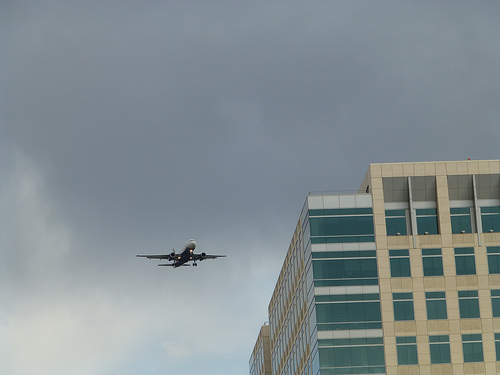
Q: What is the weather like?
A: It is cloudy.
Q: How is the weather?
A: It is cloudy.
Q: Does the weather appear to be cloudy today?
A: Yes, it is cloudy.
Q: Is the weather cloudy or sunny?
A: It is cloudy.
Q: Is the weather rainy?
A: No, it is cloudy.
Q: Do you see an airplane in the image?
A: Yes, there is an airplane.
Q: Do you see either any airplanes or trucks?
A: Yes, there is an airplane.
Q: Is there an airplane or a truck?
A: Yes, there is an airplane.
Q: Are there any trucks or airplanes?
A: Yes, there is an airplane.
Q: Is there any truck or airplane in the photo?
A: Yes, there is an airplane.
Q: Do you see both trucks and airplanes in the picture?
A: No, there is an airplane but no trucks.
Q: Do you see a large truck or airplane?
A: Yes, there is a large airplane.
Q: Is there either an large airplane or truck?
A: Yes, there is a large airplane.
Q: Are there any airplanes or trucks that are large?
A: Yes, the airplane is large.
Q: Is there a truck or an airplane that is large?
A: Yes, the airplane is large.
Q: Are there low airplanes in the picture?
A: Yes, there is a low airplane.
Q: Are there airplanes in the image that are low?
A: Yes, there is an airplane that is low.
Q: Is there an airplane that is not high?
A: Yes, there is a low airplane.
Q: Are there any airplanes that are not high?
A: Yes, there is a low airplane.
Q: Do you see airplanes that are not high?
A: Yes, there is a low airplane.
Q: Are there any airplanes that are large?
A: Yes, there is a large airplane.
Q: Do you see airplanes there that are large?
A: Yes, there is an airplane that is large.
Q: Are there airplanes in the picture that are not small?
A: Yes, there is a large airplane.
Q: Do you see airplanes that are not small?
A: Yes, there is a large airplane.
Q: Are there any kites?
A: No, there are no kites.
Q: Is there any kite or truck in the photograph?
A: No, there are no kites or trucks.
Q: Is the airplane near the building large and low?
A: Yes, the airplane is large and low.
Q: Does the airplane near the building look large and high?
A: No, the plane is large but low.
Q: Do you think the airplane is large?
A: Yes, the airplane is large.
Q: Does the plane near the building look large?
A: Yes, the airplane is large.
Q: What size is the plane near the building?
A: The plane is large.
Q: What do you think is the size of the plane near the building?
A: The plane is large.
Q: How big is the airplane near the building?
A: The plane is large.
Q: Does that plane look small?
A: No, the plane is large.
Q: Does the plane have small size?
A: No, the plane is large.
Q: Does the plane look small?
A: No, the plane is large.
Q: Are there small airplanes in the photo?
A: No, there is an airplane but it is large.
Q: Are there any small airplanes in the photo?
A: No, there is an airplane but it is large.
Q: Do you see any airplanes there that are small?
A: No, there is an airplane but it is large.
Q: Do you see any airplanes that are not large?
A: No, there is an airplane but it is large.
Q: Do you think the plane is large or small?
A: The plane is large.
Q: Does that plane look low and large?
A: Yes, the plane is low and large.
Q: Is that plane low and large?
A: Yes, the plane is low and large.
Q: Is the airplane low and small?
A: No, the airplane is low but large.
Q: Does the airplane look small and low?
A: No, the airplane is low but large.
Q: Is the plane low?
A: Yes, the plane is low.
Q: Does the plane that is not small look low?
A: Yes, the plane is low.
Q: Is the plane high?
A: No, the plane is low.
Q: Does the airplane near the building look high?
A: No, the airplane is low.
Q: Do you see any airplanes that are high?
A: No, there is an airplane but it is low.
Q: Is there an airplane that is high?
A: No, there is an airplane but it is low.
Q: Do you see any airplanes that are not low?
A: No, there is an airplane but it is low.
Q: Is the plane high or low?
A: The plane is low.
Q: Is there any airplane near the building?
A: Yes, there is an airplane near the building.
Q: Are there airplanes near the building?
A: Yes, there is an airplane near the building.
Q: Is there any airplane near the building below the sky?
A: Yes, there is an airplane near the building.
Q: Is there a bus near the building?
A: No, there is an airplane near the building.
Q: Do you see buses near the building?
A: No, there is an airplane near the building.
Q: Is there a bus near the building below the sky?
A: No, there is an airplane near the building.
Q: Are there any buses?
A: No, there are no buses.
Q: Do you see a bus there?
A: No, there are no buses.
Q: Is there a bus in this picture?
A: No, there are no buses.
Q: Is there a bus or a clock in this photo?
A: No, there are no buses or clocks.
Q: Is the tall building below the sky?
A: Yes, the building is below the sky.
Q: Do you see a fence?
A: No, there are no fences.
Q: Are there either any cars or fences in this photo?
A: No, there are no fences or cars.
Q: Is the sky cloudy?
A: Yes, the sky is cloudy.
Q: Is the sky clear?
A: No, the sky is cloudy.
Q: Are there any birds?
A: No, there are no birds.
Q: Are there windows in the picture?
A: Yes, there is a window.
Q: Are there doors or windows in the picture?
A: Yes, there is a window.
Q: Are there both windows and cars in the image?
A: No, there is a window but no cars.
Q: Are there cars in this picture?
A: No, there are no cars.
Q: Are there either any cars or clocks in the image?
A: No, there are no cars or clocks.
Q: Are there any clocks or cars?
A: No, there are no cars or clocks.